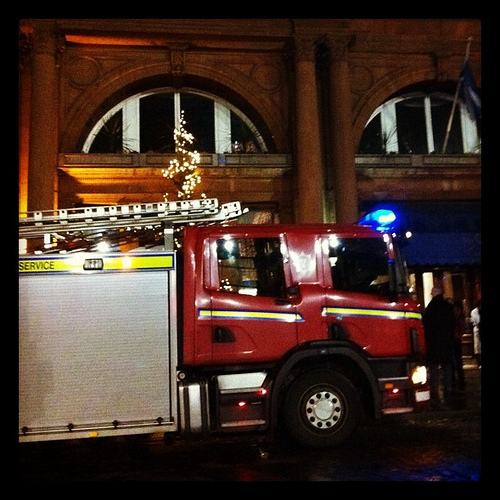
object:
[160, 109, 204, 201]
tree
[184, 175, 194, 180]
lights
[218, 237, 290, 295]
window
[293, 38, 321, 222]
column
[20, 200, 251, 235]
ladder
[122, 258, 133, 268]
light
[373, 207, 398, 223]
light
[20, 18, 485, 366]
building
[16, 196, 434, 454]
fire truck